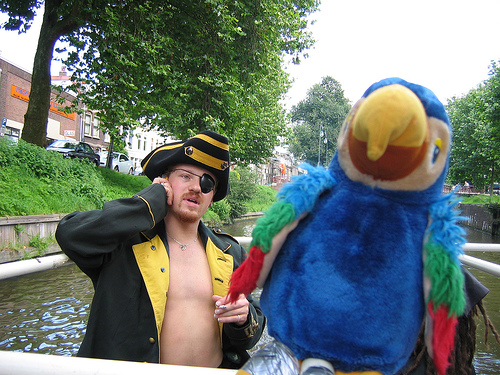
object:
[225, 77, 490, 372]
parrot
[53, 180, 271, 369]
coat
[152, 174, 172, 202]
hand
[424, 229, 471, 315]
arm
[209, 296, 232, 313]
cigarette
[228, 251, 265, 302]
red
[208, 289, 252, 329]
hand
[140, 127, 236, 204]
hat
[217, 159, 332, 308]
parrot wings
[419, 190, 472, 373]
parrot wings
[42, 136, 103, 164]
car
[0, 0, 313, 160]
tree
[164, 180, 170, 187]
ring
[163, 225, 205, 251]
necklace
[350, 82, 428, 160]
nose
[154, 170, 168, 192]
phone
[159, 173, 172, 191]
ear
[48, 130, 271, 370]
man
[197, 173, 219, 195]
eye patch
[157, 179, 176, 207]
finger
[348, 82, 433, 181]
beak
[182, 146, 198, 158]
buttons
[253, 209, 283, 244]
green